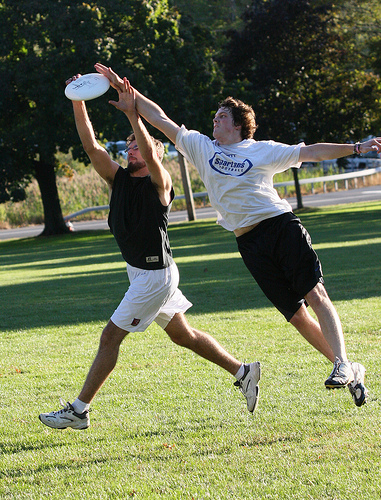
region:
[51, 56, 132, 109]
white round frisbee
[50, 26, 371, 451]
two men jumping to catch frisbee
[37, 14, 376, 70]
tall green leafy trees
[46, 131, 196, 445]
man wearing a black t-shirt and white shorts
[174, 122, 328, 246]
white t-shirt with blue logo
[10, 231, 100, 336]
shadows cast by trees on grass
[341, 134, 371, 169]
bracelets on man's left wrist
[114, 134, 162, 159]
man wearing sunglasses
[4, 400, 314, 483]
shadows cast by men jumping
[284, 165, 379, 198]
silver guardrail lining street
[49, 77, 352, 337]
two men trying to catch a frisbee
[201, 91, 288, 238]
a man wearing a white shirt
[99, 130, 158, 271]
a man wearing a black shirt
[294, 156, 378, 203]
a silver guard rail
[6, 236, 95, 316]
shadows on the grass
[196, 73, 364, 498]
a man jumping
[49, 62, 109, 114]
a white frisbee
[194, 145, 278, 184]
blue letters on a white shirt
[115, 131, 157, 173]
a man wearing glasses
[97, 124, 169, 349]
a man wearing white shorts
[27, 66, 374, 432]
two men trying to catch frisbee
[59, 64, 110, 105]
white round frisbee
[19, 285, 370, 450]
both men are mid jump to catch frisbee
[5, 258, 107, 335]
shade cast on lawn by large trees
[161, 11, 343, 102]
large green full of leaves trees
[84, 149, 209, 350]
man wearing a black t-shirt and white shorts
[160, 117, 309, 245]
white t-shirt with a blue logo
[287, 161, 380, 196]
silver metal guardrail lining street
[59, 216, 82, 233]
red and white fire hydrant behind tree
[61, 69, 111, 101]
white frisbee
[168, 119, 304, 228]
man on the right's white t-shirt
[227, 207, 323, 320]
man on the right's black shorts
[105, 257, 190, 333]
man on the left's white shorts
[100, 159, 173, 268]
man on the left's black t-shirt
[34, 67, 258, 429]
jumping man on the left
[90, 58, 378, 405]
jumping man on the right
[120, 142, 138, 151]
man on the left's glasses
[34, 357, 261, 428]
man on the left's tennis shoes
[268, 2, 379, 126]
green tree leaves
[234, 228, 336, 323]
the shorts are black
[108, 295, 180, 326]
the shorts are white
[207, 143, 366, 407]
the man is in the air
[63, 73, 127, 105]
the frisbee is white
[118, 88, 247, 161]
the man has his hand stretched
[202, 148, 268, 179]
the man has graphics on his shirt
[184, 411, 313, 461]
the grass is green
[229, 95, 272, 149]
the man has brown hair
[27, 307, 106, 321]
there is shadow on the grass